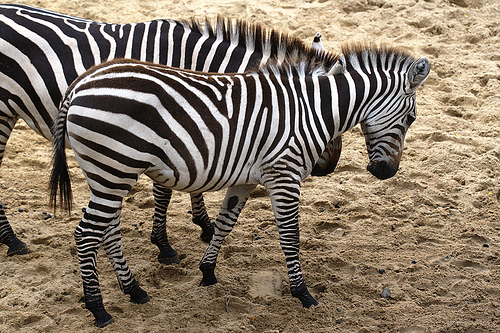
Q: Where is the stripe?
A: On the zebra.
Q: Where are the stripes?
A: On the zebras.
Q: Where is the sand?
A: On the ground.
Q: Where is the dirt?
A: On the ground.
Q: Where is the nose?
A: On the zebra.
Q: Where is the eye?
A: On the zebra.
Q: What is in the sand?
A: Zebra feet.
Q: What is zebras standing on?
A: The sand.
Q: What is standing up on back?
A: Mane.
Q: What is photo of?
A: Zebras in sand.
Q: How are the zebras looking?
A: At ground.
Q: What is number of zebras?
A: Two.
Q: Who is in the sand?
A: Zebras.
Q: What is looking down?
A: The zebra.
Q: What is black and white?
A: Stripes.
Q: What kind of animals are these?
A: Zebras.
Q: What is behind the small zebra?
A: Another zebra.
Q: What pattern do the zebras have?
A: Black and white stripes.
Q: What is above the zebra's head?
A: A mane.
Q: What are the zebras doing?
A: Walking.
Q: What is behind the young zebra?
A: An older zebra.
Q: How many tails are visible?
A: 1.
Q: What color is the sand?
A: Brown.